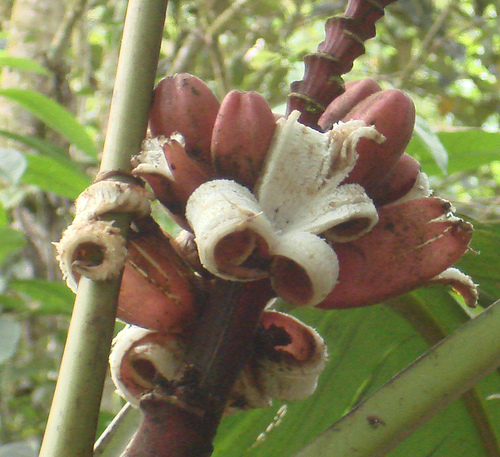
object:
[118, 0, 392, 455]
stalk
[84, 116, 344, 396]
bananas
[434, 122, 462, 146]
wall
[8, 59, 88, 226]
leaf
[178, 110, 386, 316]
peel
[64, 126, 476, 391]
peel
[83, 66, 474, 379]
bannana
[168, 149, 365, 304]
peels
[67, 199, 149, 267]
peel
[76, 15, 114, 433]
stick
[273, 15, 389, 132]
stalk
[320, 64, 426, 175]
bananas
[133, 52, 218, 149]
bananas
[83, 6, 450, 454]
tree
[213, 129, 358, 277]
peel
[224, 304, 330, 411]
peel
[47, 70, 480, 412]
banana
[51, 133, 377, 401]
bananas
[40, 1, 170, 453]
stem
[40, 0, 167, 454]
stalk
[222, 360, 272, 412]
peel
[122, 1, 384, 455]
stem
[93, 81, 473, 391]
bananas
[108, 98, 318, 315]
bananas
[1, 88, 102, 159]
leaf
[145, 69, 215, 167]
banana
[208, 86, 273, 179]
banana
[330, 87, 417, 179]
banana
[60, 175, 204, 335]
banana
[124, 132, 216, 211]
banana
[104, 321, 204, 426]
banana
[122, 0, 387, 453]
branch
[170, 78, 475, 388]
band sentence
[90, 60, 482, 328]
bananas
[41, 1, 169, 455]
branch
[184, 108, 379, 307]
peel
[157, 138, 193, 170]
peel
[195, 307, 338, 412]
banana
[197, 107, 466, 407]
banana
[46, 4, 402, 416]
tree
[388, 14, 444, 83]
branch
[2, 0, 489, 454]
tree